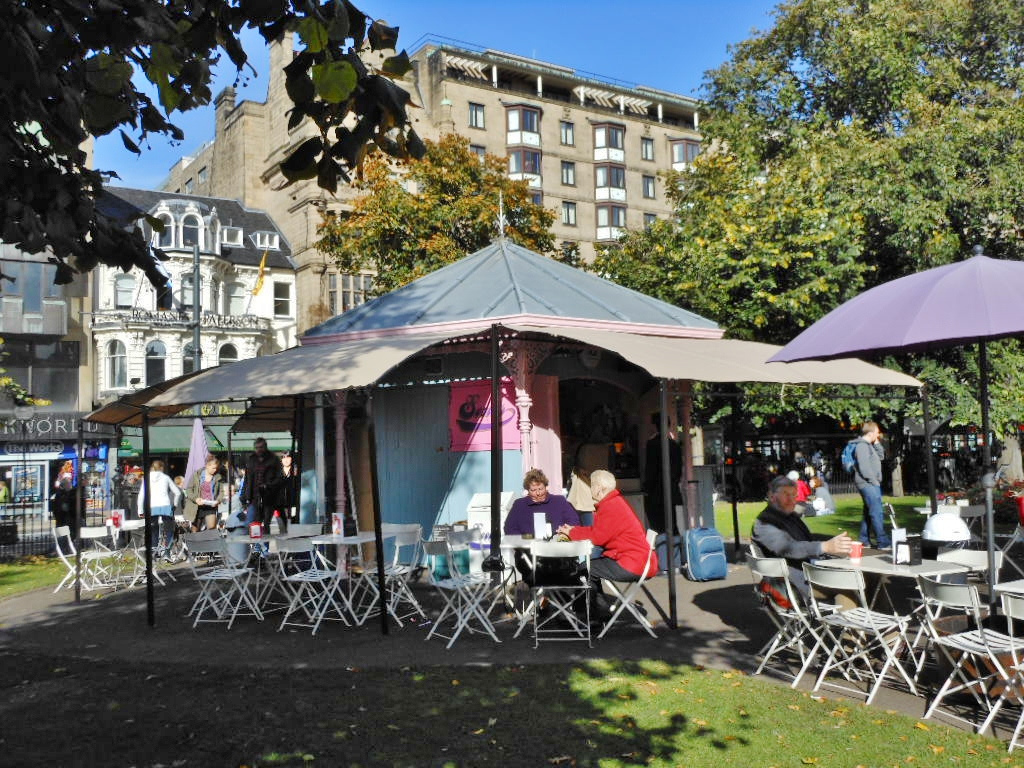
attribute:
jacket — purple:
[500, 493, 583, 535]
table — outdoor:
[807, 547, 985, 710]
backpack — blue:
[677, 525, 734, 588]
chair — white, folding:
[516, 549, 601, 656]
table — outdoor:
[464, 536, 637, 643]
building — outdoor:
[70, 215, 948, 650]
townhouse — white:
[83, 178, 300, 528]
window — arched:
[139, 329, 170, 394]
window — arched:
[183, 340, 209, 390]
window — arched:
[211, 340, 244, 371]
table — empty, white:
[314, 515, 386, 637]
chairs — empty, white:
[258, 515, 427, 639]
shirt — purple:
[502, 489, 583, 531]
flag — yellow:
[245, 245, 284, 315]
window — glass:
[267, 275, 294, 323]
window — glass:
[505, 139, 523, 172]